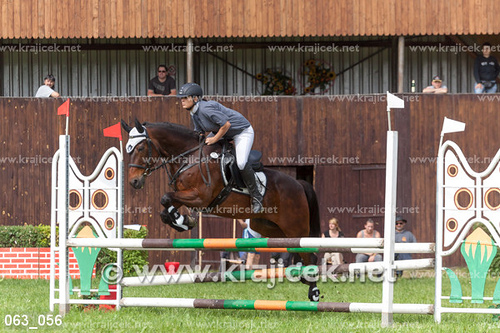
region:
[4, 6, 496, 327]
Horse jumping competition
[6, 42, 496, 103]
Spectators in the stands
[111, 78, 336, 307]
Show horse jumping a rail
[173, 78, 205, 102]
Black helmet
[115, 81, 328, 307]
Woman jumping a horse over a rail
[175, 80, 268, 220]
Woman in an english style saddle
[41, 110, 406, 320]
White rail and post with yellow, green and grey markings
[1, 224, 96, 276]
Bushes behind a red brick retaining wall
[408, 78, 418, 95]
Bottle of beer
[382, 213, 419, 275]
Man in a hat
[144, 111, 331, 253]
the hosre is brown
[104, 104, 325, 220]
the horse is jumping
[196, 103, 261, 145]
the shirt is grey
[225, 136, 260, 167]
the pants are white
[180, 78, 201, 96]
the helmet is black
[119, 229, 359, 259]
the wood is green nd orange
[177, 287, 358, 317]
the wood is blue ,orange and black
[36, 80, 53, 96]
the shirt is white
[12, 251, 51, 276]
the bricks are red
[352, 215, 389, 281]
the man has a vest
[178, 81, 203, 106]
a black helmet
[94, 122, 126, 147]
a small red flag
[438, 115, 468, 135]
a small white flag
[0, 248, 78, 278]
red and white brick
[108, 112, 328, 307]
a brown and white horse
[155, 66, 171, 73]
dark black sunglasses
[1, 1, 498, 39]
part of a brown fence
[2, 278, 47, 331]
a section of green grass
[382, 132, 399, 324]
a tall white pole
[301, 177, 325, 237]
a black horse tail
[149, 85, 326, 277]
The man riding the horse.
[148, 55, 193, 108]
Man watching the race.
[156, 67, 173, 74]
The man wearing sunglasses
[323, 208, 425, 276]
People sitting by the wall.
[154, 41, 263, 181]
Jockey on the horse.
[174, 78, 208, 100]
The jockey is wearing a helmet.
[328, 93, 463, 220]
The wall is made of wood.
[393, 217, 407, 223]
A man is wearing hat.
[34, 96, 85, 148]
Red flags on the pole.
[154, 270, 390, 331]
The grass is green.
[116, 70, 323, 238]
a woman jumping a horse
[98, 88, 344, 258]
a jumping horse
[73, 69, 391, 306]
a horse jumping over hurdles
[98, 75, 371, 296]
a brown horse jumping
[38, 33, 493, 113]
spectators watching the horse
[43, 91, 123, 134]
red flag markers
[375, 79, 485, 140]
white flag markers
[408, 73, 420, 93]
a bottle of beer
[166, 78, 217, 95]
a black riding helmet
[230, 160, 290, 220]
black riding boots